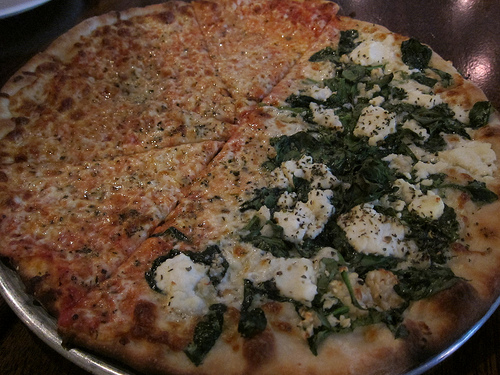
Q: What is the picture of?
A: Pizza.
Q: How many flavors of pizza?
A: Two.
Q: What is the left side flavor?
A: Cheese.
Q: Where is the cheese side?
A: Left side.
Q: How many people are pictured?
A: 0.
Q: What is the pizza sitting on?
A: A pan.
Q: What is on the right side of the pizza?
A: Spinach.